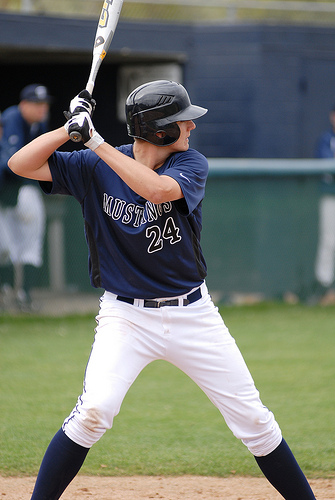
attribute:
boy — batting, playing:
[65, 67, 253, 368]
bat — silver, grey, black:
[86, 0, 120, 78]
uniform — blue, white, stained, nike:
[74, 155, 269, 480]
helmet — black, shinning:
[117, 68, 210, 117]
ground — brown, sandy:
[128, 477, 214, 500]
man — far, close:
[3, 82, 50, 120]